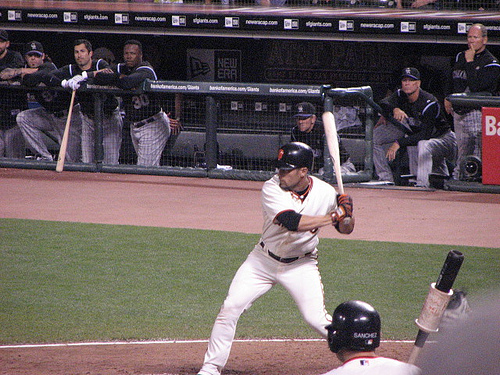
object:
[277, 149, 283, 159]
ornament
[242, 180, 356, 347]
uniform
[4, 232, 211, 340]
grass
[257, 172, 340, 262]
jersey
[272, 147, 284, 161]
logo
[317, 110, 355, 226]
baseball bat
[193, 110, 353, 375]
baseball player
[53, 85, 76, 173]
bat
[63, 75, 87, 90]
hands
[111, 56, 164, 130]
jersey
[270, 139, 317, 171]
helmet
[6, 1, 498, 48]
dugout roof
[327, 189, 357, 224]
hands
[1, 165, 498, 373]
ground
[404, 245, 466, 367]
bat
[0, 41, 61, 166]
player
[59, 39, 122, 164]
player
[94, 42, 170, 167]
player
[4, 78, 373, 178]
railing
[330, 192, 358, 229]
gloves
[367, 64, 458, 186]
team member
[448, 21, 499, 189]
team member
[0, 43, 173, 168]
team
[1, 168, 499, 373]
dirt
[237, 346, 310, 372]
dirt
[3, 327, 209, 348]
line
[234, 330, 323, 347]
line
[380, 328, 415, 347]
line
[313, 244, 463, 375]
baseball player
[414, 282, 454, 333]
weight trainer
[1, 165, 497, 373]
field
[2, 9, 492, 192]
dugout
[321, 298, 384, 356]
helmet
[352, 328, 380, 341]
sanchez